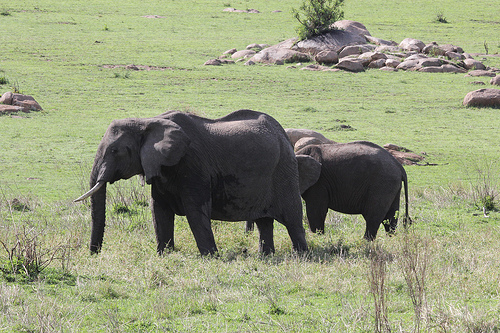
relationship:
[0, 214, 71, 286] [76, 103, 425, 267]
bush by elephants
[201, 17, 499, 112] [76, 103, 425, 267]
rocks behind elephants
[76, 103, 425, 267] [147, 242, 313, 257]
elephants have feet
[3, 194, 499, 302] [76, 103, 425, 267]
grass below elephants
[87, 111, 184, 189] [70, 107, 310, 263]
head of elephant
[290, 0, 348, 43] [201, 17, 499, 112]
plant on rocks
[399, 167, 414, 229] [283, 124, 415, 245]
tail of elephant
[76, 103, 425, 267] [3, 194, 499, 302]
elephants in grass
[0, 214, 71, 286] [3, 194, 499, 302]
bush in grass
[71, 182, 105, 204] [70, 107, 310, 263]
tusk of elephant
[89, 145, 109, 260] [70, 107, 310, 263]
trunk of elephant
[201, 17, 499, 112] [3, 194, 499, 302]
rocks in grass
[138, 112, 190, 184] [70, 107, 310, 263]
ears of elephant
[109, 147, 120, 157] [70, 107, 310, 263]
eye of elephant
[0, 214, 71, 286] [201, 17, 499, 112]
bush in rocks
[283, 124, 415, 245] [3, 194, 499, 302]
elephant in grass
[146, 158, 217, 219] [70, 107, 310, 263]
chest of elephant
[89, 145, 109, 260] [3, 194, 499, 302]
trunk in grass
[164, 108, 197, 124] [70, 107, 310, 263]
hump on elephant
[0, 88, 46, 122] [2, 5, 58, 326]
rocks on left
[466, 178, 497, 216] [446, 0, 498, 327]
tuft on right